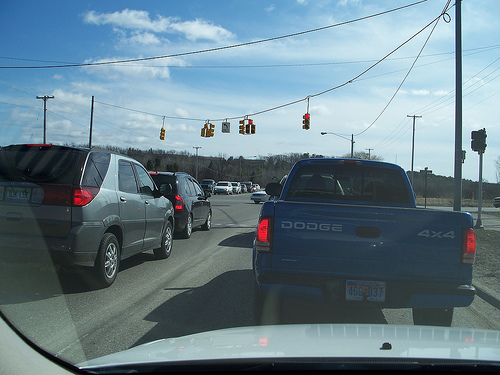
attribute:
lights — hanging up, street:
[150, 110, 321, 143]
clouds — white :
[28, 6, 227, 140]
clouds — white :
[82, 17, 230, 57]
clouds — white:
[61, 3, 236, 87]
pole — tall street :
[428, 9, 498, 261]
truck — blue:
[220, 139, 484, 309]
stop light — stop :
[133, 91, 339, 161]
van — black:
[145, 169, 213, 240]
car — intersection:
[211, 180, 231, 192]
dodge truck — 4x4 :
[253, 195, 488, 309]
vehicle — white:
[236, 123, 498, 342]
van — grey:
[0, 142, 176, 289]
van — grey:
[148, 169, 210, 239]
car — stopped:
[148, 163, 213, 235]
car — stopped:
[249, 153, 474, 322]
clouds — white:
[123, 19, 300, 86]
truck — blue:
[252, 157, 473, 316]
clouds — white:
[82, 7, 236, 77]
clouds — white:
[2, 79, 202, 149]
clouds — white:
[361, 81, 495, 121]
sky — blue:
[4, 2, 494, 153]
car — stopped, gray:
[1, 145, 175, 288]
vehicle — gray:
[0, 145, 173, 282]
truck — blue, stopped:
[247, 146, 479, 327]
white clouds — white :
[293, 12, 414, 58]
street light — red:
[304, 112, 309, 129]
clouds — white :
[361, 60, 428, 162]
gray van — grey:
[0, 137, 177, 285]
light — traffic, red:
[302, 111, 309, 131]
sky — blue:
[6, 6, 492, 195]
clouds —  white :
[80, 53, 162, 85]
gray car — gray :
[0, 142, 178, 287]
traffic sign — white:
[174, 117, 273, 164]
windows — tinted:
[10, 144, 120, 198]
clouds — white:
[80, 6, 239, 46]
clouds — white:
[72, 54, 172, 85]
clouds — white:
[215, 14, 483, 74]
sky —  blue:
[225, 20, 287, 52]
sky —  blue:
[9, 16, 68, 50]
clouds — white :
[185, 21, 240, 56]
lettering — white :
[270, 216, 351, 241]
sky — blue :
[9, 7, 92, 52]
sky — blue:
[12, 25, 67, 53]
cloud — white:
[324, 40, 394, 66]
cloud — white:
[375, 86, 432, 116]